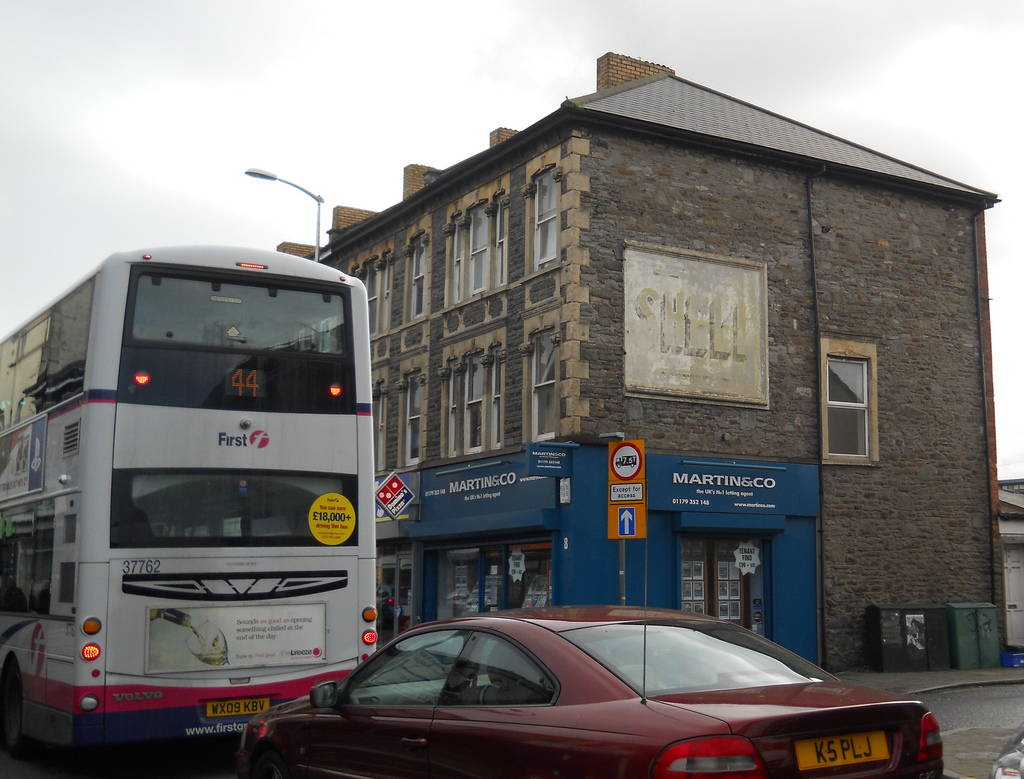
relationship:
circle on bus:
[272, 474, 398, 563] [0, 225, 396, 643]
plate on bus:
[183, 655, 289, 716] [47, 240, 335, 755]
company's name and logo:
[193, 426, 246, 450] [242, 422, 269, 459]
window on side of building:
[791, 325, 902, 483] [316, 87, 991, 682]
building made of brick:
[316, 87, 991, 682] [845, 465, 967, 571]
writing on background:
[651, 467, 790, 520] [635, 450, 813, 528]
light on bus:
[76, 629, 118, 666] [15, 225, 387, 723]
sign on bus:
[288, 482, 360, 556] [15, 225, 387, 723]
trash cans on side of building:
[852, 594, 1019, 700] [316, 87, 991, 682]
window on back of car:
[540, 612, 834, 695] [255, 567, 947, 766]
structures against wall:
[864, 577, 1003, 688] [808, 472, 1009, 687]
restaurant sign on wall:
[359, 465, 414, 528] [383, 208, 565, 606]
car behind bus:
[243, 610, 946, 773] [26, 227, 426, 733]